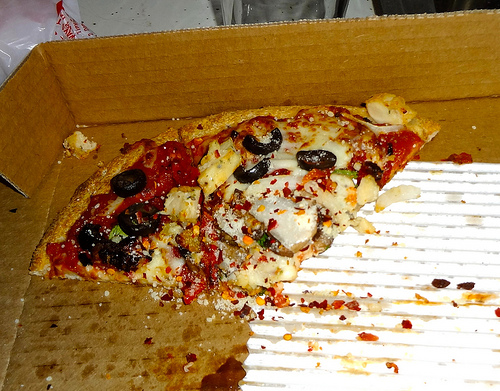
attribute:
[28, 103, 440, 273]
crust — golden, baked, pizza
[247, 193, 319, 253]
cheese — piece, mozzarella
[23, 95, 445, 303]
pizza — thin, sliced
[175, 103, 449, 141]
crust — dark brown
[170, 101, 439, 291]
pizza — slice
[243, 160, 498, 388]
box liner — cardboard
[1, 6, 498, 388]
container — cardboard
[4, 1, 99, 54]
plastic bag — white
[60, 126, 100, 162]
crumb — pizza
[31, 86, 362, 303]
olives — black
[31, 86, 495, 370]
pizza — fully cooked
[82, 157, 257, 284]
pizza — partially, left over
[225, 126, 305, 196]
olives — black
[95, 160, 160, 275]
olives — black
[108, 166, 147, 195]
olives — black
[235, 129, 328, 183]
olives — sliced, black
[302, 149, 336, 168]
olive — black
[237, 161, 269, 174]
olive — black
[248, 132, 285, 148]
olive — black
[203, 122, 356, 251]
cheese — white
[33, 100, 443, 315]
pizza — brown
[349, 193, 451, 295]
paper — white 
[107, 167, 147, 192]
slice — black, round, olive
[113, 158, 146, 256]
olives — black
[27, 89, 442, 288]
pizza — baked, less than half, remaining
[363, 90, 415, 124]
mushroom — sliced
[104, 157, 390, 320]
toppings — many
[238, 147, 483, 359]
liner — white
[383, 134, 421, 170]
sauce — pizza